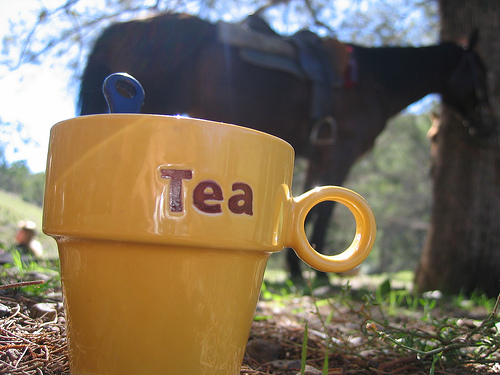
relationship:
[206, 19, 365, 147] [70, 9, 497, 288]
saddle on horse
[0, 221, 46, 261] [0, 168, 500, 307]
person in grass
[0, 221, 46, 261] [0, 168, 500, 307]
person sitting in grass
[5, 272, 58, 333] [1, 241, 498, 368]
bundle on ground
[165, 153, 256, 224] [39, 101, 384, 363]
letters on pot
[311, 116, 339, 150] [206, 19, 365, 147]
stirrup on saddle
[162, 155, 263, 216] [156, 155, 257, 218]
tea in red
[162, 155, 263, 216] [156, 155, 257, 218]
tea written in red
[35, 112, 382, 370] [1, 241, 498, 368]
mug on ground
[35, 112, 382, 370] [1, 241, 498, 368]
mug sitting on ground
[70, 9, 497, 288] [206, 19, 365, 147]
horse wearing saddle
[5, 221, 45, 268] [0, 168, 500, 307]
person in grass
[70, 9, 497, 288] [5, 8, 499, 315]
horse under tree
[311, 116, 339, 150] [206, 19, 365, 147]
stirrup for saddle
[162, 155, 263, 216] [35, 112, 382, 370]
tea written on mug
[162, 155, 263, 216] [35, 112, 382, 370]
tea on mug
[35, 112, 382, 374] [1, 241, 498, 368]
mug on ground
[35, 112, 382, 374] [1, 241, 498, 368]
mug sitting on ground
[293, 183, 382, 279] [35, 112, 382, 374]
handle on mug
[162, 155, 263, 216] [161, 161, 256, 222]
tea written in brown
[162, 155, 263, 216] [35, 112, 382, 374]
tea on mug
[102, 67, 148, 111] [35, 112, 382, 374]
handle out of mug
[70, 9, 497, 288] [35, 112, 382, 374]
horse behind mug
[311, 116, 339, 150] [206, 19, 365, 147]
stirrup attached to saddle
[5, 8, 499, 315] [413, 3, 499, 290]
tree has trunk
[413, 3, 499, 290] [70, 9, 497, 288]
trunk next to horse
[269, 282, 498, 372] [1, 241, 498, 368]
weeds on ground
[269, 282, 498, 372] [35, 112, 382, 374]
weeds near mug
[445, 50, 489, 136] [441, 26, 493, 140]
bridle around head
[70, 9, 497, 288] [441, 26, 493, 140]
horse has head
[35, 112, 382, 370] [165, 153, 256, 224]
mug with letters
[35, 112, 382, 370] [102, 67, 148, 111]
mug has handle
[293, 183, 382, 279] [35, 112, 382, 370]
handle on mug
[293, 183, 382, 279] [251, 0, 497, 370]
handle pointing to right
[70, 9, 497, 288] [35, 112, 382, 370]
horse behind mug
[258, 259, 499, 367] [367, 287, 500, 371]
plant has part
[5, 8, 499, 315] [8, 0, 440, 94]
tree has edge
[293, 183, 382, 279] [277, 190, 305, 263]
handle has part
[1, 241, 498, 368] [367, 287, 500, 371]
ground has part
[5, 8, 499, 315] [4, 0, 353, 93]
tree has part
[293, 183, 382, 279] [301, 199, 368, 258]
handle has edge